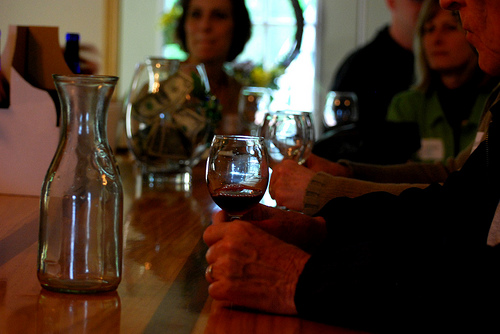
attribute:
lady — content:
[164, 3, 252, 68]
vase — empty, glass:
[31, 70, 131, 302]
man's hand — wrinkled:
[201, 215, 310, 319]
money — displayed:
[140, 79, 195, 157]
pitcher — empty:
[31, 70, 124, 300]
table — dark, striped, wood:
[7, 188, 337, 332]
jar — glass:
[114, 50, 223, 177]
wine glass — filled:
[200, 131, 268, 224]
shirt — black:
[303, 119, 498, 331]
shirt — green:
[386, 76, 487, 153]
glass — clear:
[200, 130, 269, 223]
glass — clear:
[260, 110, 313, 169]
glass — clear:
[297, 107, 315, 165]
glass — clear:
[317, 84, 362, 128]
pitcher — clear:
[32, 67, 134, 298]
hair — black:
[231, 3, 252, 53]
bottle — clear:
[34, 64, 126, 298]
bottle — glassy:
[37, 71, 124, 289]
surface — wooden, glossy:
[1, 189, 292, 328]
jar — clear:
[120, 57, 219, 173]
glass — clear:
[31, 67, 123, 291]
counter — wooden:
[2, 189, 303, 332]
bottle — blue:
[61, 30, 90, 76]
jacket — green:
[383, 80, 494, 180]